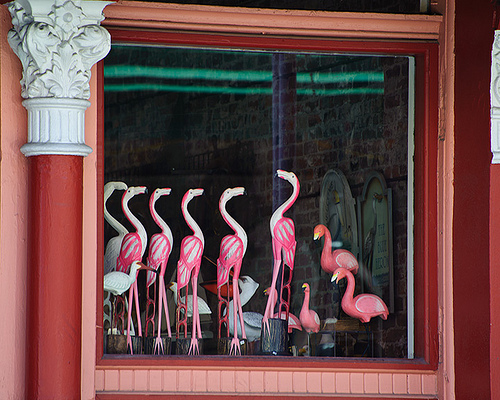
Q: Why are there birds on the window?
A: They are there for decoration.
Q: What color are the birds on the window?
A: Pink and white.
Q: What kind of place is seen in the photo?
A: A building.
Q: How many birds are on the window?
A: Nine.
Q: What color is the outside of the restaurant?
A: Red and white.